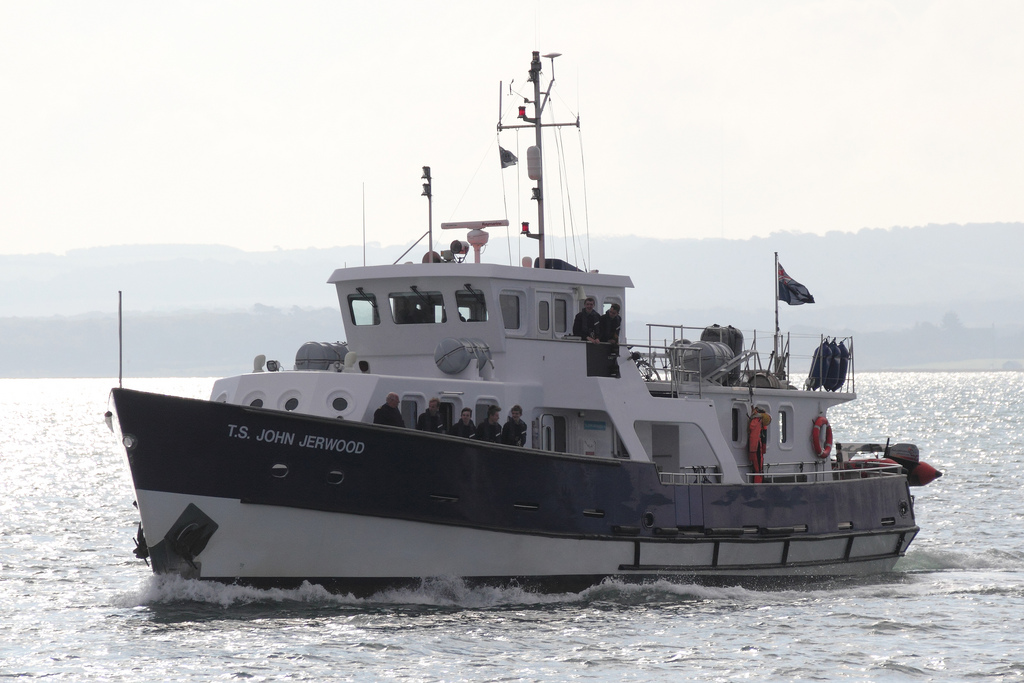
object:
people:
[592, 303, 620, 378]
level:
[323, 263, 874, 400]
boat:
[104, 51, 944, 602]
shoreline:
[0, 220, 1024, 377]